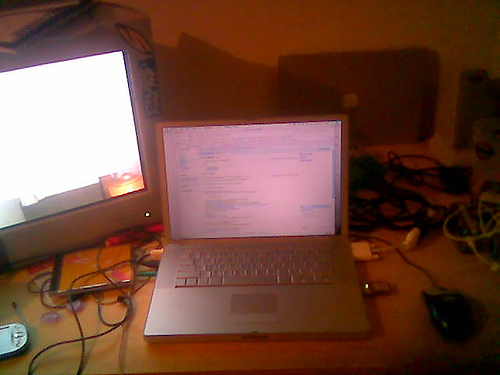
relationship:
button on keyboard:
[278, 275, 291, 285] [163, 237, 348, 286]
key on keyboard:
[186, 277, 197, 286] [168, 246, 342, 291]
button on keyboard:
[278, 275, 291, 285] [182, 242, 331, 300]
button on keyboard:
[275, 270, 295, 288] [169, 240, 343, 290]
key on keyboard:
[175, 271, 201, 278] [176, 247, 338, 292]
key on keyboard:
[186, 277, 197, 286] [177, 245, 346, 286]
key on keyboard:
[222, 267, 237, 276] [172, 242, 340, 288]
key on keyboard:
[222, 270, 233, 276] [173, 245, 350, 290]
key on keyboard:
[192, 253, 202, 268] [159, 229, 410, 294]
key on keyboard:
[194, 259, 204, 265] [176, 247, 337, 287]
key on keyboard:
[222, 270, 233, 276] [137, 95, 379, 353]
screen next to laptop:
[163, 117, 350, 236] [141, 104, 391, 349]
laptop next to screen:
[141, 104, 391, 349] [163, 117, 350, 236]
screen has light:
[12, 55, 156, 250] [0, 77, 132, 173]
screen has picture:
[12, 55, 156, 250] [84, 166, 149, 190]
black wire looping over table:
[30, 231, 154, 373] [0, 187, 494, 372]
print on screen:
[182, 143, 314, 218] [148, 117, 350, 237]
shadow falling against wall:
[187, 46, 266, 109] [163, 15, 323, 94]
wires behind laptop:
[348, 156, 491, 225] [147, 119, 384, 346]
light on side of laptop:
[356, 279, 370, 294] [147, 119, 384, 346]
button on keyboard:
[278, 275, 291, 285] [177, 245, 346, 286]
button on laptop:
[278, 275, 291, 285] [213, 107, 379, 256]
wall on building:
[150, 2, 498, 166] [129, 2, 498, 169]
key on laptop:
[222, 276, 277, 285] [141, 104, 391, 349]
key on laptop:
[185, 277, 197, 288] [141, 110, 375, 342]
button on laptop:
[278, 275, 291, 285] [141, 110, 375, 342]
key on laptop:
[175, 267, 202, 274] [162, 131, 360, 327]